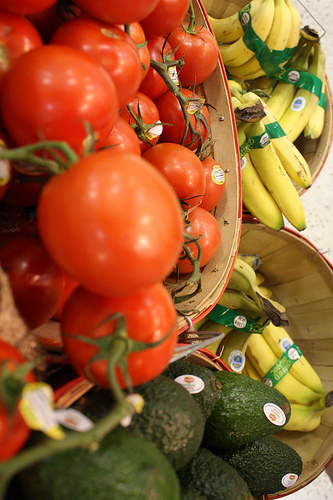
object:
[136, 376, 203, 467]
avacado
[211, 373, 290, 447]
avacado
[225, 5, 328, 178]
basket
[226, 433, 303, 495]
avacado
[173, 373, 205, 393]
avacado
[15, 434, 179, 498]
avacado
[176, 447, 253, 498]
avacado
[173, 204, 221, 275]
tomato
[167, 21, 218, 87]
tomato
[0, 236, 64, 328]
tomato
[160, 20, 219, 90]
tomato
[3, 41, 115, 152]
tomato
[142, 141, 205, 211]
tomato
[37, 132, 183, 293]
tomato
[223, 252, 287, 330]
bananas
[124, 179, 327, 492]
basket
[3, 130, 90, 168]
stem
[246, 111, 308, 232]
banana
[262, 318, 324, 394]
banana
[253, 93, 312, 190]
banana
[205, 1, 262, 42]
banana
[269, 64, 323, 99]
stripe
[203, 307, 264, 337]
stripe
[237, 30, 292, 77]
stripe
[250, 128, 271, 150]
stripe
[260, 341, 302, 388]
stripe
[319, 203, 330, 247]
ground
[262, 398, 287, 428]
sticker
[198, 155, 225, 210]
tomato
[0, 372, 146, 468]
stem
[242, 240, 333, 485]
basket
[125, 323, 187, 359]
leaf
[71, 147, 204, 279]
tomaaaaaaatoes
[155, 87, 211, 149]
tomato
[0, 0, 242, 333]
basket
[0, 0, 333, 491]
view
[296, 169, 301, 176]
bruise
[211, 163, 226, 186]
sticker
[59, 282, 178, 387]
tomato